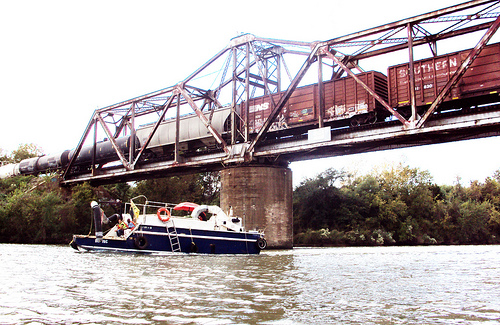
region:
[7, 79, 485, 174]
Multi-car train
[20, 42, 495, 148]
The train is on a bridge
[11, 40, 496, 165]
The train is rusty and the paint is chipping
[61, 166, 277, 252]
There is a boat in the water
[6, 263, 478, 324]
The water is dark and murky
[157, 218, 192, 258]
Ladder hanging off the boat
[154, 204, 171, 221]
Orange life preserver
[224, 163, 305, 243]
Wide stone pillar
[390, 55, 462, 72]
The word southern is on the train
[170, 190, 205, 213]
Red umbrella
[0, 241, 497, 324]
the body of water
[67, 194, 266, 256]
the boat on the water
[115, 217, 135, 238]
the people on the boat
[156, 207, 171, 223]
the life saver on the boat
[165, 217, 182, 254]
the ladder on the boat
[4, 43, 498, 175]
the train on the track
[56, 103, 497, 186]
the bridge above the water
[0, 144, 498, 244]
the trees along the water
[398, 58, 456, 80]
the large letters on the side of the train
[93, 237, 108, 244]
the letters and/or numbers on the side of the boat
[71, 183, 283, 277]
boat in the water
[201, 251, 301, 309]
shadow in the water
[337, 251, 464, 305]
water under a bridge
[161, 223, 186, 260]
ladder on a boat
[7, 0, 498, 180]
train on a bridge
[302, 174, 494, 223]
green leaves on trees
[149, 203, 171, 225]
life preserver on a boat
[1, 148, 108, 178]
train on train tracks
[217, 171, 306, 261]
cement pier for a bridge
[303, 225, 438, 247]
rocks along side of water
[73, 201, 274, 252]
a blue and white boat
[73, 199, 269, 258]
a blue and white boat on the water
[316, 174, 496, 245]
a bushy tree line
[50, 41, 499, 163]
a train on a bridge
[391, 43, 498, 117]
a red box car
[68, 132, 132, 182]
a black tanker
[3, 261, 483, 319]
a brown muddy water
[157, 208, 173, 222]
a orange life saver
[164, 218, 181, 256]
a ladder on a boat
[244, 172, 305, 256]
a concrete pillar in the watre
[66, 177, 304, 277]
a blue and white boat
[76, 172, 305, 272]
a boat floating in the water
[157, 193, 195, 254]
a ladder on the side of the boat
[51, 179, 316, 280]
a boat floating in the water near a bridge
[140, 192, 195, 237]
a life raft on a boat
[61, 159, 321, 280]
a boat passing under a bridge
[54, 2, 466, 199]
a train passing over a bridge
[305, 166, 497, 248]
a heavily wooded area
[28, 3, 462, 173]
lots of train cars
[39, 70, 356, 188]
a train on train tracks